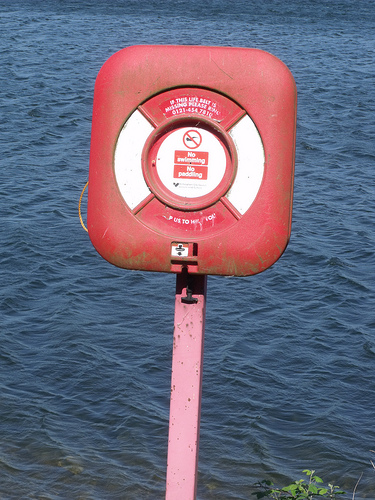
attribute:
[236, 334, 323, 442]
water — BLUE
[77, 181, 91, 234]
wire — PIECE, STRAY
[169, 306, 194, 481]
paint — FADED, RED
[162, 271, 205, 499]
post — rusty, metal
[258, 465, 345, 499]
plant — green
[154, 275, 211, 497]
post — rusty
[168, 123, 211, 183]
signs — warning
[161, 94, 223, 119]
telephone number — displayed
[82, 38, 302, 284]
stand — LIFE BELT, EMPTY, red, white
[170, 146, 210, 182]
signs — red, white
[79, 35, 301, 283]
sign — RED, WHITE, square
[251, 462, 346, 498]
plant — green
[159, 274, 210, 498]
pole — chipped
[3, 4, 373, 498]
lake — large, blue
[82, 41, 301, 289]
life preserver — red, white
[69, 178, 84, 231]
string — yellow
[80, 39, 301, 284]
safety equipment — red, white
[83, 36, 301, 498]
device — red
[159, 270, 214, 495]
pole — WEATHERED , PINK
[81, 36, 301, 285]
device — red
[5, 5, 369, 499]
water — calm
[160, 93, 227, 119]
lettering — white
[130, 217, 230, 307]
latch — red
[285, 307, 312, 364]
water — choppy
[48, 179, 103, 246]
string — yellow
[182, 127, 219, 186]
sign — red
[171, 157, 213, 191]
sign — red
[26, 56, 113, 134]
water — blue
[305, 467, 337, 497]
plant — green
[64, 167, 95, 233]
cord — yellow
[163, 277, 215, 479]
arm — pink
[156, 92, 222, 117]
number — white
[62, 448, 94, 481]
rock — submerged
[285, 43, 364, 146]
water — choppy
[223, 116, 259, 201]
portion — white